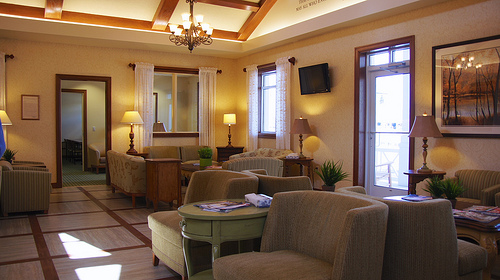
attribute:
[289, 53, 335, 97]
television — flat, screen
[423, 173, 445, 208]
plant — green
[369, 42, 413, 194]
door — glass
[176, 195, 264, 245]
table — small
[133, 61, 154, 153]
curatin — white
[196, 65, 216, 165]
curatin — white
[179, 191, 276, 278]
table — round, green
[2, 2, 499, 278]
waiting room — neat, clean, Light colored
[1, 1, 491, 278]
room — large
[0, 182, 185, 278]
floor — tan, checker pattern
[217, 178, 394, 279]
chair — tan, circular, padded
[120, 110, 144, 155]
lamp — small